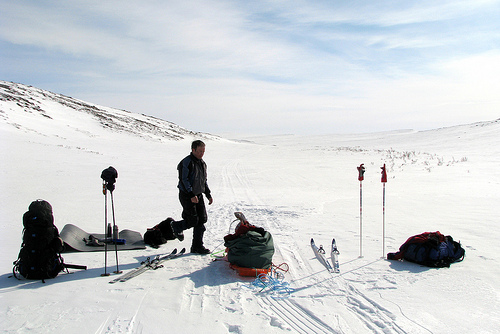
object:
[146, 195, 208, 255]
pants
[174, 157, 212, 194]
coat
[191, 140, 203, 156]
hair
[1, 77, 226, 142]
land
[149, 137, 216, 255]
man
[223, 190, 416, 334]
track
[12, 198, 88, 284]
pack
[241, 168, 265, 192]
broken branches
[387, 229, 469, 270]
bag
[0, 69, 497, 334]
snow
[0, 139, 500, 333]
ground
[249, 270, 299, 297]
rope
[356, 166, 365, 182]
handles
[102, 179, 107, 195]
handles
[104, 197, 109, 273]
poles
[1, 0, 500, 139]
cloud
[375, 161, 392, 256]
pole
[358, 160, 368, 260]
pole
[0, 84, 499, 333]
hill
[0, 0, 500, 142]
sky